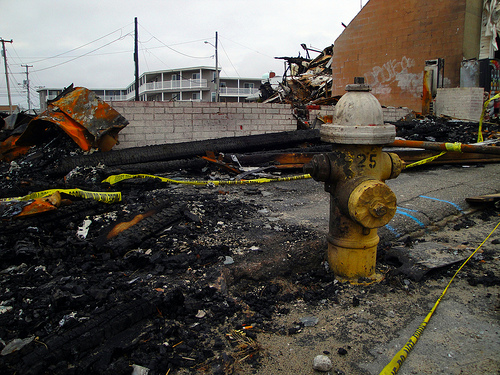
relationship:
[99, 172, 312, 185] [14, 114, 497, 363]
police tape on ground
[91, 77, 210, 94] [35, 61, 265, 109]
balcony of building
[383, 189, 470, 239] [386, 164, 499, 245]
stripes on curb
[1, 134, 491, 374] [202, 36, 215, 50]
street a lamp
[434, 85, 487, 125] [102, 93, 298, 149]
block concrete wall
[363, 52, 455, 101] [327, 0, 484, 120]
graffiti on building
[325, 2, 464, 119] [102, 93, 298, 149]
brick sloped wall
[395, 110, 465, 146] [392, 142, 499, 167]
charred length wood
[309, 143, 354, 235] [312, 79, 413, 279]
blackened fire hydrant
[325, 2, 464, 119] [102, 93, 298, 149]
brick on wall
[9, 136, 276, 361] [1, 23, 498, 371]
fire a scene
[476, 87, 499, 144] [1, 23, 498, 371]
stripe for scene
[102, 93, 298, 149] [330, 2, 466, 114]
wall of bricks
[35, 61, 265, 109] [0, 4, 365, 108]
building in background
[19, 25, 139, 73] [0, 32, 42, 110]
lines and posts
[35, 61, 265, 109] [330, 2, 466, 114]
building of bricks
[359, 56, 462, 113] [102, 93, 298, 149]
writing on wall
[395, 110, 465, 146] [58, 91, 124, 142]
charred fire remnants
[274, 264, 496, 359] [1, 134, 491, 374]
section of street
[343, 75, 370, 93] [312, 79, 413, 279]
top of hydrant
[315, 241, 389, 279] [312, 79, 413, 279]
bottom of hydrant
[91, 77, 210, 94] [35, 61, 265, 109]
balcony in building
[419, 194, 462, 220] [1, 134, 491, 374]
marking on street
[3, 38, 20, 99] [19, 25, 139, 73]
telephone several lines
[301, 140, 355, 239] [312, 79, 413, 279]
blackened fire hydrant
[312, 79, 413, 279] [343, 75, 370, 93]
hydrant has top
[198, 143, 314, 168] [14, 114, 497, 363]
debris on ground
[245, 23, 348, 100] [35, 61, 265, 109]
debris behind building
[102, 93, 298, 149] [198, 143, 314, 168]
wall between debris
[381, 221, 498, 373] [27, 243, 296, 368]
police tape stewed on ground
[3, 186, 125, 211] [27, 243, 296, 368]
police tape stewed on ground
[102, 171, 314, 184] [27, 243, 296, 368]
police tape stewed on ground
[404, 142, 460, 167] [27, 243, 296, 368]
police tape stewed on ground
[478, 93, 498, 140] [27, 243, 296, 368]
police tape stewed on ground